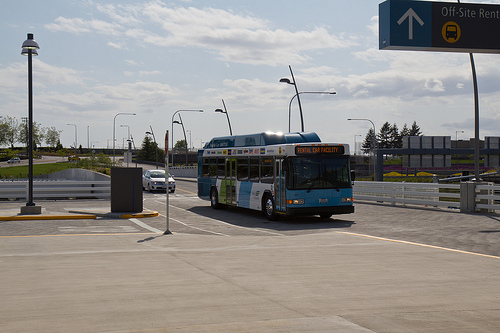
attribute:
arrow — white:
[395, 6, 425, 41]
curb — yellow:
[1, 210, 161, 220]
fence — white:
[0, 179, 111, 199]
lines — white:
[127, 218, 163, 234]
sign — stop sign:
[161, 129, 175, 239]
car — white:
[143, 169, 176, 191]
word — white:
[163, 140, 169, 150]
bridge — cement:
[48, 165, 205, 198]